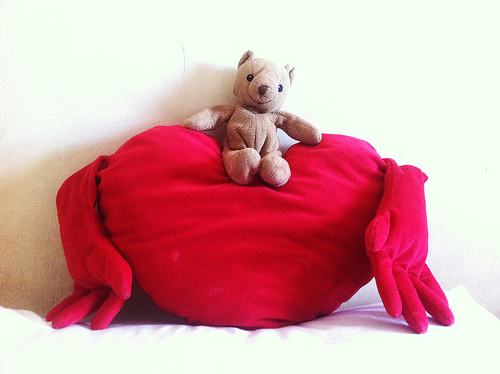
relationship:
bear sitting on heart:
[185, 50, 322, 186] [39, 114, 454, 334]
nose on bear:
[257, 83, 266, 97] [185, 50, 322, 186]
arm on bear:
[181, 103, 240, 133] [185, 50, 322, 186]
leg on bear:
[224, 147, 262, 183] [185, 50, 322, 186]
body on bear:
[186, 105, 321, 185] [193, 34, 321, 183]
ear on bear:
[236, 41, 257, 68] [190, 39, 316, 179]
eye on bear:
[244, 70, 253, 81] [185, 50, 322, 186]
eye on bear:
[277, 82, 284, 93] [185, 50, 322, 186]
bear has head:
[185, 50, 322, 186] [231, 48, 298, 113]